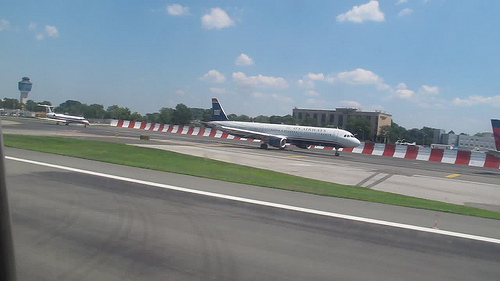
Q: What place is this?
A: It is a runway.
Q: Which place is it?
A: It is a runway.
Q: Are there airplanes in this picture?
A: Yes, there is an airplane.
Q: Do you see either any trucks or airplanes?
A: Yes, there is an airplane.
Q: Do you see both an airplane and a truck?
A: No, there is an airplane but no trucks.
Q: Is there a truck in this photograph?
A: No, there are no trucks.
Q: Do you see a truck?
A: No, there are no trucks.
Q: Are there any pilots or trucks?
A: No, there are no trucks or pilots.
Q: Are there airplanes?
A: Yes, there is an airplane.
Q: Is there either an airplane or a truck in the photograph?
A: Yes, there is an airplane.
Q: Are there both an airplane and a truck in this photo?
A: No, there is an airplane but no trucks.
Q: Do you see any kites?
A: No, there are no kites.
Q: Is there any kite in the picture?
A: No, there are no kites.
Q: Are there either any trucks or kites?
A: No, there are no kites or trucks.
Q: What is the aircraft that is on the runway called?
A: The aircraft is an airplane.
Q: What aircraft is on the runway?
A: The aircraft is an airplane.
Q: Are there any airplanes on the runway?
A: Yes, there is an airplane on the runway.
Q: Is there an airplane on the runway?
A: Yes, there is an airplane on the runway.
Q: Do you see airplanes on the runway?
A: Yes, there is an airplane on the runway.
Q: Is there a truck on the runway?
A: No, there is an airplane on the runway.